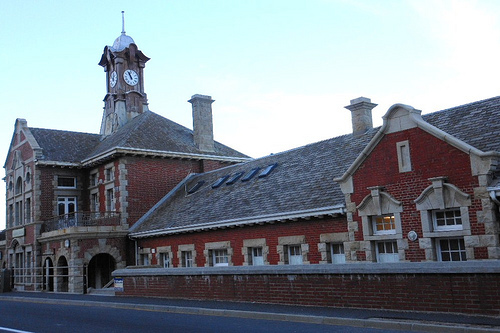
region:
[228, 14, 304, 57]
blue sky above building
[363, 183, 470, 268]
windows on building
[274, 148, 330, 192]
roof of the building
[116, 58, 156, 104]
clock on the building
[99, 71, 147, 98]
two clock faces on building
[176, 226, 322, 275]
windows in a row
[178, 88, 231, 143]
chimney on the roof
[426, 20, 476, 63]
lightest part of the sky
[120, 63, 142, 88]
hands on the clock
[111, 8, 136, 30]
tip of the clock tower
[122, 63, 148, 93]
the clock is white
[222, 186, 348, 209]
the roof is brick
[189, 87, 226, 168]
the chimney is brick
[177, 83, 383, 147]
two chimneys on buildings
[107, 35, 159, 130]
clock is on tower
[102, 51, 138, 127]
the tower is stone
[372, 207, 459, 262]
windows on the building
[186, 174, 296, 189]
windows on the roof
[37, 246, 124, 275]
the archways are stone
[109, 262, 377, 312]
the wall is brick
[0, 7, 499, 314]
a large brick building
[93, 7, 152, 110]
a clock tower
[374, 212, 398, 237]
light seen through window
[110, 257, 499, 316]
long short brick wall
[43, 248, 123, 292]
open archways of building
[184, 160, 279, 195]
skylights on roof of building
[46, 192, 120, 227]
white door closed to balcony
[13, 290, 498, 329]
sidewalk in front of building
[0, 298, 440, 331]
half of a street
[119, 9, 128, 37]
spire on top of clock tower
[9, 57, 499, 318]
a unique building on the street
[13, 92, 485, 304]
this building is made out of red brick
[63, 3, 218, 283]
there is a small tower clock on top of the structure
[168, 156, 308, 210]
this building has solar panels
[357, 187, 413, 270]
the light is on in this building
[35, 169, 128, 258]
this building has a balcony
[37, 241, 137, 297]
this is an entrance way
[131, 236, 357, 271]
a row of windows on the building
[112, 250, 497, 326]
a brick gate in front of the eficie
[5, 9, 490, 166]
a hazy sky over the structure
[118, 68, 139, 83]
white clock ticking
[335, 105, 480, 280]
red brick aging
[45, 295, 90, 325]
black street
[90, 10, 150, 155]
clock tower stands tall in the sky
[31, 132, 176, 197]
old building experiences the sands of time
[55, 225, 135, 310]
building entrance has a dark entryway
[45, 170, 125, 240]
grey balcony for having parties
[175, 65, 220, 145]
grey chimney with no smoke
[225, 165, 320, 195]
grey roof needs some work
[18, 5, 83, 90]
blue sky changes to a white hue